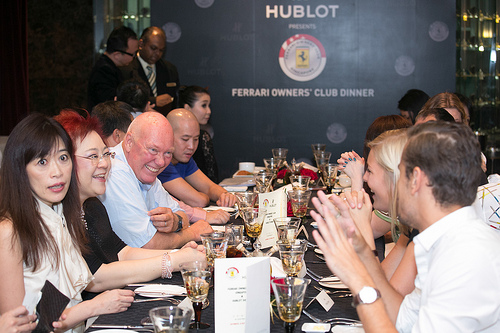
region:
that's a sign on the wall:
[148, 0, 457, 182]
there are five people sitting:
[0, 84, 243, 331]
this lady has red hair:
[54, 108, 113, 198]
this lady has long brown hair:
[1, 110, 136, 330]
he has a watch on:
[349, 284, 382, 306]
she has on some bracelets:
[158, 248, 173, 280]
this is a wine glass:
[269, 275, 313, 331]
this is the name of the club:
[225, 86, 377, 98]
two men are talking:
[90, 20, 177, 114]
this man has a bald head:
[120, 108, 177, 184]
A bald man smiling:
[122, 110, 176, 185]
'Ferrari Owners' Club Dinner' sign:
[229, 83, 376, 99]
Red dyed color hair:
[52, 104, 106, 149]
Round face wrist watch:
[348, 282, 383, 308]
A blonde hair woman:
[362, 125, 394, 212]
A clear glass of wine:
[180, 267, 212, 331]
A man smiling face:
[136, 140, 173, 177]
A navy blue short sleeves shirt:
[158, 157, 199, 184]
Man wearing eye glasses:
[103, 23, 139, 67]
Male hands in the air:
[309, 188, 366, 283]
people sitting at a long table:
[1, 84, 496, 330]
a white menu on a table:
[214, 256, 269, 331]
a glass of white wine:
[271, 278, 311, 332]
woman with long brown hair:
[0, 113, 95, 271]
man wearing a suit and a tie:
[121, 25, 178, 108]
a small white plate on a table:
[136, 282, 186, 297]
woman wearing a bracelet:
[160, 250, 174, 280]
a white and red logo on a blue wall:
[278, 34, 327, 81]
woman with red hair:
[63, 105, 125, 262]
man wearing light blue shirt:
[108, 105, 180, 247]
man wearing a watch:
[340, 120, 487, 329]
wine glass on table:
[267, 273, 303, 325]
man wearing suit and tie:
[125, 13, 172, 100]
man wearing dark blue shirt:
[160, 106, 215, 211]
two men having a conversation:
[85, 8, 177, 103]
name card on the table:
[308, 281, 335, 311]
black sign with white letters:
[155, 3, 457, 120]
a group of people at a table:
[7, 76, 494, 321]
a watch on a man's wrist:
[352, 280, 386, 307]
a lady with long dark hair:
[3, 103, 84, 327]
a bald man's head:
[125, 107, 177, 183]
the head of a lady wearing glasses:
[69, 113, 114, 197]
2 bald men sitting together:
[124, 105, 205, 215]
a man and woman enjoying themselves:
[357, 124, 488, 319]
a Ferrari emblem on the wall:
[274, 30, 331, 83]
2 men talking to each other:
[92, 16, 182, 91]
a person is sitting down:
[2, 115, 135, 326]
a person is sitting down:
[60, 110, 207, 288]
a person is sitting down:
[101, 112, 215, 249]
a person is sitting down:
[163, 107, 238, 209]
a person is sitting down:
[183, 90, 215, 172]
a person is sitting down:
[308, 119, 498, 331]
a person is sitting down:
[336, 128, 418, 292]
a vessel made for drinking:
[271, 274, 308, 324]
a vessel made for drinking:
[181, 261, 213, 331]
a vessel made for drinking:
[278, 238, 303, 275]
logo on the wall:
[265, 26, 333, 81]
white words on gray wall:
[220, 79, 381, 101]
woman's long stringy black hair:
[7, 125, 87, 247]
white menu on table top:
[203, 249, 285, 321]